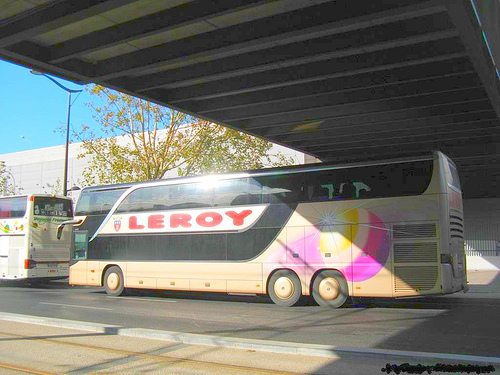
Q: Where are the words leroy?
A: On the buss.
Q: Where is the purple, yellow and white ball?
A: On the bus.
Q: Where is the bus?
A: Under a bridge.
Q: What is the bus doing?
A: Parked.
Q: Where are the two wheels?
A: On the back of the bus.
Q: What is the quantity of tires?
A: Three.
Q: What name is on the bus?
A: Leroy.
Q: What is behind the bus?
A: A tree.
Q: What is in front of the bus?
A: Another bus.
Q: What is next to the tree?
A: A light pole.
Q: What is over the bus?
A: A bridge.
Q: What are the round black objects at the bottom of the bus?
A: The tires.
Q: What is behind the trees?
A: A building.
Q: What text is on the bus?
A: Leroy.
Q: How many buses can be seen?
A: Three.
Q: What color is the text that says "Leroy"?
A: Red.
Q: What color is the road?
A: Grey.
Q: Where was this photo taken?
A: A street.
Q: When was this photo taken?
A: Daytime.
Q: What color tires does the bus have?
A: Black.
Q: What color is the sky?
A: Blue.